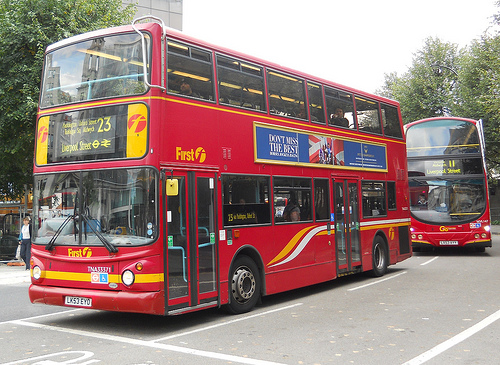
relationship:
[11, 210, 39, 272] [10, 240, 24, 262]
lady holding bag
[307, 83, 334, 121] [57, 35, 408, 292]
window on bus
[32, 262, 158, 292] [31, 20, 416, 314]
yellow line on bus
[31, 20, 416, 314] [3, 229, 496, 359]
bus on street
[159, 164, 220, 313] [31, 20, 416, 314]
door on bus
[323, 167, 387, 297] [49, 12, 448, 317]
door on bus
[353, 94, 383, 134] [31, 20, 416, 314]
window on bus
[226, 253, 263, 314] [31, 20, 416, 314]
tire a part of bus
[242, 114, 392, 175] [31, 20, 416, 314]
sign on side of bus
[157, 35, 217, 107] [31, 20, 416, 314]
window on bus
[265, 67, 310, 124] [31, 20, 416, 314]
window on bus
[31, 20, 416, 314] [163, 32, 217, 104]
bus has window